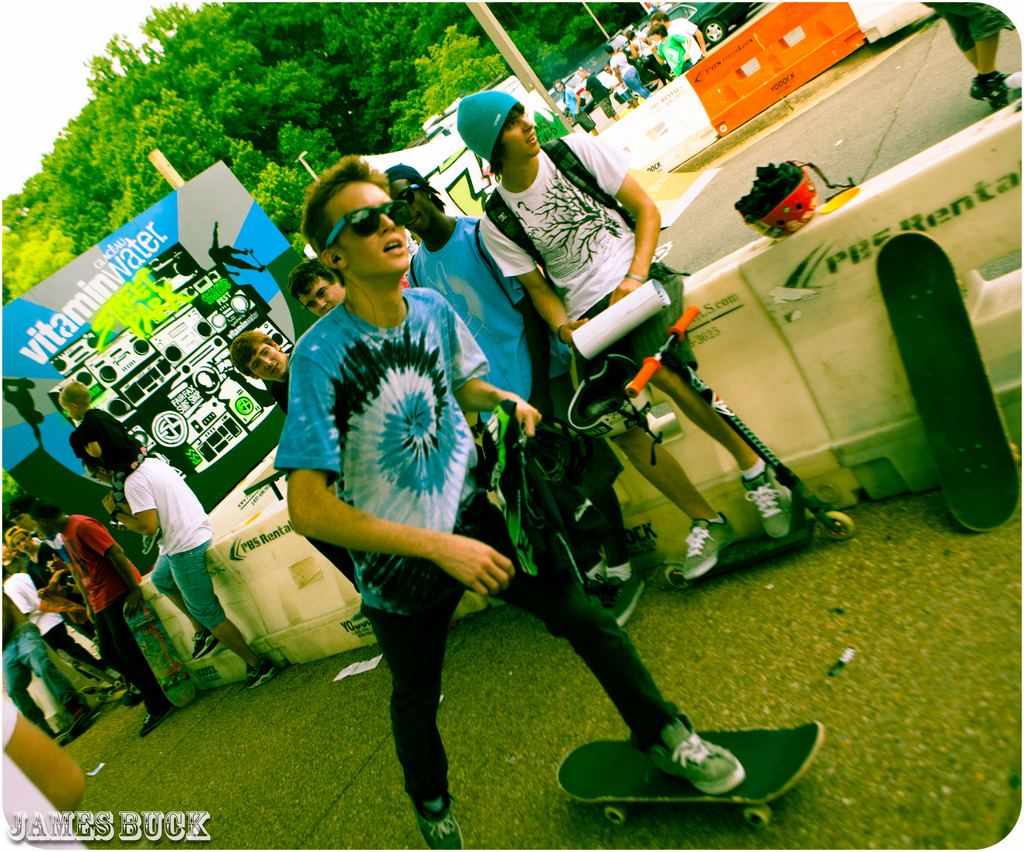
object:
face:
[325, 180, 410, 274]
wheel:
[603, 804, 628, 826]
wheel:
[744, 804, 772, 830]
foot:
[649, 717, 747, 796]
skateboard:
[555, 721, 824, 828]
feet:
[740, 463, 790, 538]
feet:
[682, 513, 739, 581]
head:
[457, 90, 540, 175]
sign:
[17, 222, 296, 478]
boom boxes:
[46, 242, 293, 482]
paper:
[332, 655, 382, 683]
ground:
[50, 468, 1024, 849]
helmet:
[567, 353, 665, 466]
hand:
[559, 317, 587, 348]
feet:
[359, 556, 680, 822]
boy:
[274, 152, 747, 851]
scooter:
[622, 305, 855, 589]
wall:
[66, 131, 1022, 700]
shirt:
[273, 284, 492, 616]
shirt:
[58, 514, 145, 614]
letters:
[91, 267, 200, 354]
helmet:
[720, 168, 840, 249]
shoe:
[583, 566, 646, 626]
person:
[228, 328, 293, 417]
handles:
[625, 305, 701, 399]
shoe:
[682, 511, 740, 580]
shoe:
[742, 463, 794, 538]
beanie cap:
[455, 90, 520, 163]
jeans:
[361, 490, 679, 805]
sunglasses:
[326, 199, 413, 250]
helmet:
[734, 160, 855, 239]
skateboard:
[877, 232, 1019, 533]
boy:
[455, 90, 792, 583]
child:
[57, 379, 145, 531]